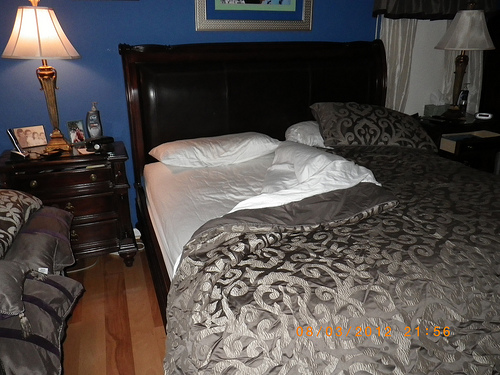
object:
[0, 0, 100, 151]
light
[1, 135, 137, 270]
table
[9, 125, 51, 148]
picture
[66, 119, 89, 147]
picture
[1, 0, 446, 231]
wall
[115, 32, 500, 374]
bed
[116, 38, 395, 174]
headboard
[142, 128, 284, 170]
pillows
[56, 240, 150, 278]
wire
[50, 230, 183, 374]
floor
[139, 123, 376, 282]
linens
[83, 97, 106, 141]
bottle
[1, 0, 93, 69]
shade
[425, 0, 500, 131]
light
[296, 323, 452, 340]
stamp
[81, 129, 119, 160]
phone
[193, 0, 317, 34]
frame